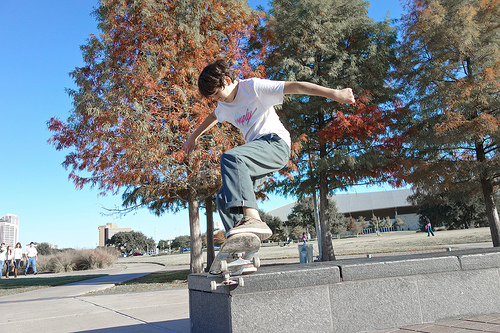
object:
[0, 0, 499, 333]
scene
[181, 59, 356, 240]
boy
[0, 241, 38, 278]
people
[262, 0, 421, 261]
trees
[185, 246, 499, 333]
wall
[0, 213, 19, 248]
buildings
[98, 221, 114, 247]
buildings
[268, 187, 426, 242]
house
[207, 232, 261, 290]
skateboard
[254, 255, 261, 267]
wheel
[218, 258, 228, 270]
wheel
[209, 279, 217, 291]
wheel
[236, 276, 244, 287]
wheel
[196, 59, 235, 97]
hair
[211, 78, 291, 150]
shirt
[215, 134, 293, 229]
pants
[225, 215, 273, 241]
shoes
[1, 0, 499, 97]
sky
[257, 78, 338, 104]
arm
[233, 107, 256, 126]
lettering